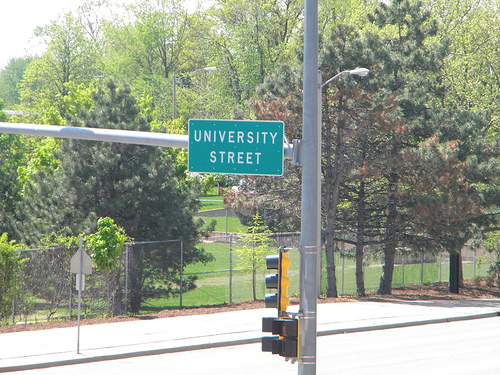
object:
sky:
[32, 2, 68, 10]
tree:
[253, 25, 296, 50]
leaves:
[379, 39, 392, 66]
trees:
[123, 26, 134, 37]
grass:
[211, 285, 249, 296]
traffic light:
[260, 248, 298, 359]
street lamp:
[316, 60, 384, 95]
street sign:
[187, 118, 284, 177]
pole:
[0, 120, 187, 148]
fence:
[207, 229, 252, 261]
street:
[356, 345, 418, 374]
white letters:
[266, 130, 278, 146]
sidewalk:
[178, 318, 239, 335]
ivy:
[87, 233, 141, 264]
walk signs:
[260, 318, 298, 355]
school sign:
[65, 240, 92, 275]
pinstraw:
[435, 287, 449, 291]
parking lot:
[214, 209, 215, 213]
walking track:
[194, 273, 235, 290]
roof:
[31, 8, 85, 61]